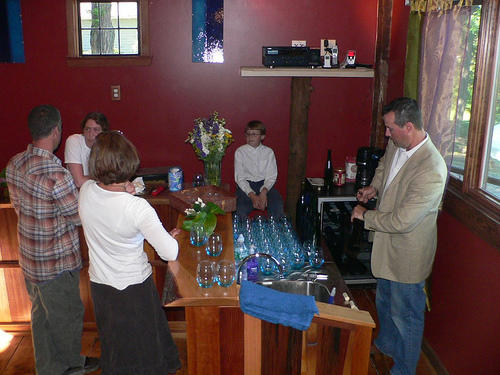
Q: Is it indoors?
A: Yes, it is indoors.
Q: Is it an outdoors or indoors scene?
A: It is indoors.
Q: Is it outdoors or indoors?
A: It is indoors.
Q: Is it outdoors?
A: No, it is indoors.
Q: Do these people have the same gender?
A: No, they are both male and female.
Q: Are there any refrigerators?
A: Yes, there is a refrigerator.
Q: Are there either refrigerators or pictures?
A: Yes, there is a refrigerator.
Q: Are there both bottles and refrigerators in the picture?
A: Yes, there are both a refrigerator and a bottle.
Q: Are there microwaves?
A: No, there are no microwaves.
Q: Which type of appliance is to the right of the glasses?
A: The appliance is a refrigerator.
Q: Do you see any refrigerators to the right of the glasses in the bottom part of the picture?
A: Yes, there is a refrigerator to the right of the glasses.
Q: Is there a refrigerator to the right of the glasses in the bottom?
A: Yes, there is a refrigerator to the right of the glasses.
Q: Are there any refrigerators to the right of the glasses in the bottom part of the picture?
A: Yes, there is a refrigerator to the right of the glasses.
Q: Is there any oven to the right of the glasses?
A: No, there is a refrigerator to the right of the glasses.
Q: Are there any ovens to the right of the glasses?
A: No, there is a refrigerator to the right of the glasses.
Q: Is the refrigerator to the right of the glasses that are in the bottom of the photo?
A: Yes, the refrigerator is to the right of the glasses.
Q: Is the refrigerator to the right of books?
A: No, the refrigerator is to the right of the glasses.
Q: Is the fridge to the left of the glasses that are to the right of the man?
A: No, the fridge is to the right of the glasses.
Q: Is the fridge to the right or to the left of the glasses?
A: The fridge is to the right of the glasses.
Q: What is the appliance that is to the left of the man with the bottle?
A: The appliance is a refrigerator.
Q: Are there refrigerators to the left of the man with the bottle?
A: Yes, there is a refrigerator to the left of the man.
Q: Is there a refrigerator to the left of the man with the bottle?
A: Yes, there is a refrigerator to the left of the man.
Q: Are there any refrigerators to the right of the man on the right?
A: No, the refrigerator is to the left of the man.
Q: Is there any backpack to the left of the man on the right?
A: No, there is a refrigerator to the left of the man.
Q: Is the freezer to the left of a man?
A: Yes, the freezer is to the left of a man.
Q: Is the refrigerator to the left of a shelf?
A: No, the refrigerator is to the left of a man.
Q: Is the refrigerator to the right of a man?
A: No, the refrigerator is to the left of a man.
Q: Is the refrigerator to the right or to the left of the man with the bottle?
A: The refrigerator is to the left of the man.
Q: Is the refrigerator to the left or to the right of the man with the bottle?
A: The refrigerator is to the left of the man.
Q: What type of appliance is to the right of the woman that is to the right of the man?
A: The appliance is a refrigerator.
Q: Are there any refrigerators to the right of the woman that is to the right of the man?
A: Yes, there is a refrigerator to the right of the woman.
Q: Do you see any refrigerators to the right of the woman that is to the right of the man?
A: Yes, there is a refrigerator to the right of the woman.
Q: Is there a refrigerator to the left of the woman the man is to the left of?
A: No, the refrigerator is to the right of the woman.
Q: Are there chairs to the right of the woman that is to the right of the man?
A: No, there is a refrigerator to the right of the woman.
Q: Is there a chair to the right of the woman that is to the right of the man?
A: No, there is a refrigerator to the right of the woman.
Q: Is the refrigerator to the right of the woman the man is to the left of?
A: Yes, the refrigerator is to the right of the woman.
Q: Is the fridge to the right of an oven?
A: No, the fridge is to the right of the woman.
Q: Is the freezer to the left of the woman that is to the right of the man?
A: No, the freezer is to the right of the woman.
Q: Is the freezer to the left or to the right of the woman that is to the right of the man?
A: The freezer is to the right of the woman.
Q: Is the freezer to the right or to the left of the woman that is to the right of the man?
A: The freezer is to the right of the woman.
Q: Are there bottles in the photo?
A: Yes, there is a bottle.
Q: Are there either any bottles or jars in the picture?
A: Yes, there is a bottle.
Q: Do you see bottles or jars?
A: Yes, there is a bottle.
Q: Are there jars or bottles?
A: Yes, there is a bottle.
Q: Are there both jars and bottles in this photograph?
A: No, there is a bottle but no jars.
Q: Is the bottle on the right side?
A: Yes, the bottle is on the right of the image.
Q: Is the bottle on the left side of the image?
A: No, the bottle is on the right of the image.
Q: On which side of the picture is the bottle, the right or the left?
A: The bottle is on the right of the image.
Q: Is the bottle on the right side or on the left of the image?
A: The bottle is on the right of the image.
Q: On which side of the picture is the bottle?
A: The bottle is on the right of the image.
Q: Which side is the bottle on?
A: The bottle is on the right of the image.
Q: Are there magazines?
A: No, there are no magazines.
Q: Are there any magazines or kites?
A: No, there are no magazines or kites.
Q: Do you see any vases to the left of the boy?
A: Yes, there is a vase to the left of the boy.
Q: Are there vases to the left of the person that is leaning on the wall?
A: Yes, there is a vase to the left of the boy.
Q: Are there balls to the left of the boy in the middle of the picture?
A: No, there is a vase to the left of the boy.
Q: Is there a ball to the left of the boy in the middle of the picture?
A: No, there is a vase to the left of the boy.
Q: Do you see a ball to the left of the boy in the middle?
A: No, there is a vase to the left of the boy.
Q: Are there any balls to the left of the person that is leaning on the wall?
A: No, there is a vase to the left of the boy.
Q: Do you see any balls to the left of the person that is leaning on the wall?
A: No, there is a vase to the left of the boy.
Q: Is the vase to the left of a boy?
A: Yes, the vase is to the left of a boy.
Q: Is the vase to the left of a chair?
A: No, the vase is to the left of a boy.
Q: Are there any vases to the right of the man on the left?
A: Yes, there is a vase to the right of the man.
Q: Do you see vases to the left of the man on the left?
A: No, the vase is to the right of the man.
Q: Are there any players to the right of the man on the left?
A: No, there is a vase to the right of the man.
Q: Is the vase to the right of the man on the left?
A: Yes, the vase is to the right of the man.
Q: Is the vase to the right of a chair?
A: No, the vase is to the right of the man.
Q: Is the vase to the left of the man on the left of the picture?
A: No, the vase is to the right of the man.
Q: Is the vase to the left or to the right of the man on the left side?
A: The vase is to the right of the man.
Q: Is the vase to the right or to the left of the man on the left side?
A: The vase is to the right of the man.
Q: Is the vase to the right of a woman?
A: Yes, the vase is to the right of a woman.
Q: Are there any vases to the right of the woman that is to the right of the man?
A: Yes, there is a vase to the right of the woman.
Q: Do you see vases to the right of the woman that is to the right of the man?
A: Yes, there is a vase to the right of the woman.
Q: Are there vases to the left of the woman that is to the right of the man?
A: No, the vase is to the right of the woman.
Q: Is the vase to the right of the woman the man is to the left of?
A: Yes, the vase is to the right of the woman.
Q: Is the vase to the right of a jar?
A: No, the vase is to the right of the woman.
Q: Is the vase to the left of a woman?
A: No, the vase is to the right of a woman.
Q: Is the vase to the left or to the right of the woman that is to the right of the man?
A: The vase is to the right of the woman.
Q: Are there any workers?
A: No, there are no workers.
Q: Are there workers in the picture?
A: No, there are no workers.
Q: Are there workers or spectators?
A: No, there are no workers or spectators.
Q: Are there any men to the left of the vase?
A: Yes, there is a man to the left of the vase.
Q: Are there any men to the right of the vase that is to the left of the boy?
A: No, the man is to the left of the vase.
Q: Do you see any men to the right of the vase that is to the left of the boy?
A: No, the man is to the left of the vase.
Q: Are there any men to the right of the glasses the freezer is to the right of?
A: No, the man is to the left of the glasses.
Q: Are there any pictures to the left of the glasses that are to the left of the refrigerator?
A: No, there is a man to the left of the glasses.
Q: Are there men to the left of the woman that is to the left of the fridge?
A: Yes, there is a man to the left of the woman.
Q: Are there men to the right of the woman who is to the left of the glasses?
A: No, the man is to the left of the woman.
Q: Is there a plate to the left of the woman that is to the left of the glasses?
A: No, there is a man to the left of the woman.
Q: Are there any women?
A: Yes, there is a woman.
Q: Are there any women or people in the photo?
A: Yes, there is a woman.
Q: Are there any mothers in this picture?
A: No, there are no mothers.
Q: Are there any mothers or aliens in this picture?
A: No, there are no mothers or aliens.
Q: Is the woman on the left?
A: Yes, the woman is on the left of the image.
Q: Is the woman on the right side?
A: No, the woman is on the left of the image.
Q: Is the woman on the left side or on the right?
A: The woman is on the left of the image.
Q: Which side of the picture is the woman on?
A: The woman is on the left of the image.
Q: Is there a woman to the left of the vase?
A: Yes, there is a woman to the left of the vase.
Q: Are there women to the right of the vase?
A: No, the woman is to the left of the vase.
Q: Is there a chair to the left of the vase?
A: No, there is a woman to the left of the vase.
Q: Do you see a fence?
A: No, there are no fences.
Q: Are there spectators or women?
A: Yes, there is a woman.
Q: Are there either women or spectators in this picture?
A: Yes, there is a woman.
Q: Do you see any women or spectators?
A: Yes, there is a woman.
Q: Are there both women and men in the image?
A: Yes, there are both a woman and a man.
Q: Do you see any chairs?
A: No, there are no chairs.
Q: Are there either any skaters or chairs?
A: No, there are no chairs or skaters.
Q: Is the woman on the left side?
A: Yes, the woman is on the left of the image.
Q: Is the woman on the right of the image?
A: No, the woman is on the left of the image.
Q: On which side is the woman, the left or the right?
A: The woman is on the left of the image.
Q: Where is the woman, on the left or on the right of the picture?
A: The woman is on the left of the image.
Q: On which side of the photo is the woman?
A: The woman is on the left of the image.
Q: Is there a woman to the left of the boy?
A: Yes, there is a woman to the left of the boy.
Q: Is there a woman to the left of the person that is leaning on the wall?
A: Yes, there is a woman to the left of the boy.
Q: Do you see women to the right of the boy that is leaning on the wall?
A: No, the woman is to the left of the boy.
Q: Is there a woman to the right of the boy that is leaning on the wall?
A: No, the woman is to the left of the boy.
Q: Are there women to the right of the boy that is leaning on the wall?
A: No, the woman is to the left of the boy.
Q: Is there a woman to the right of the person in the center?
A: No, the woman is to the left of the boy.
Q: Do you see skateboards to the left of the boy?
A: No, there is a woman to the left of the boy.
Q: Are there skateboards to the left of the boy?
A: No, there is a woman to the left of the boy.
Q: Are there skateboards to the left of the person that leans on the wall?
A: No, there is a woman to the left of the boy.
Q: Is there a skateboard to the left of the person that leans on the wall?
A: No, there is a woman to the left of the boy.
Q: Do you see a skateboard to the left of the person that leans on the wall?
A: No, there is a woman to the left of the boy.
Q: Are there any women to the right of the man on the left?
A: Yes, there is a woman to the right of the man.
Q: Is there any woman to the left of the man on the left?
A: No, the woman is to the right of the man.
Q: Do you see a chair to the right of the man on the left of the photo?
A: No, there is a woman to the right of the man.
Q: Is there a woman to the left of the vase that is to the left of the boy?
A: Yes, there is a woman to the left of the vase.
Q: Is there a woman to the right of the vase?
A: No, the woman is to the left of the vase.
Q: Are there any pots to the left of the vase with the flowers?
A: No, there is a woman to the left of the vase.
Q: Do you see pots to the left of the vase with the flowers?
A: No, there is a woman to the left of the vase.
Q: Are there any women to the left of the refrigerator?
A: Yes, there is a woman to the left of the refrigerator.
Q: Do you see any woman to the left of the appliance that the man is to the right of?
A: Yes, there is a woman to the left of the refrigerator.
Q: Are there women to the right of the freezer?
A: No, the woman is to the left of the freezer.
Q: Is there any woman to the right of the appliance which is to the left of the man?
A: No, the woman is to the left of the freezer.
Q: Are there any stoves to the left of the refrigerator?
A: No, there is a woman to the left of the refrigerator.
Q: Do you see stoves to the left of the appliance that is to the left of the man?
A: No, there is a woman to the left of the refrigerator.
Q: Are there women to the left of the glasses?
A: Yes, there is a woman to the left of the glasses.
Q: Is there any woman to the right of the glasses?
A: No, the woman is to the left of the glasses.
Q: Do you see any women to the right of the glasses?
A: No, the woman is to the left of the glasses.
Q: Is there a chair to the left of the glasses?
A: No, there is a woman to the left of the glasses.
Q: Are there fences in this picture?
A: No, there are no fences.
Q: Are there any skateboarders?
A: No, there are no skateboarders.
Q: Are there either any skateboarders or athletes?
A: No, there are no skateboarders or athletes.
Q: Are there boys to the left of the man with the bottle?
A: Yes, there is a boy to the left of the man.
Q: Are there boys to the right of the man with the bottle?
A: No, the boy is to the left of the man.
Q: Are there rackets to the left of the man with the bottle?
A: No, there is a boy to the left of the man.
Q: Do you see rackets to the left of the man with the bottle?
A: No, there is a boy to the left of the man.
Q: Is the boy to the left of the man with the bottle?
A: Yes, the boy is to the left of the man.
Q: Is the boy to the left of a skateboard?
A: No, the boy is to the left of the man.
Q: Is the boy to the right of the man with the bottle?
A: No, the boy is to the left of the man.